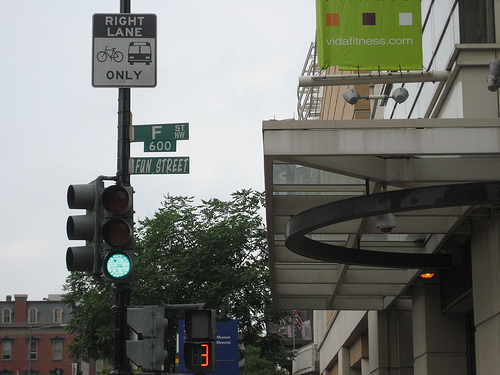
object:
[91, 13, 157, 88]
sign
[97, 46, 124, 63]
bike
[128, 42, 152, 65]
bus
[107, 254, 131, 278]
light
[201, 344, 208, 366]
three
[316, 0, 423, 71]
sign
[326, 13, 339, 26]
square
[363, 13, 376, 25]
square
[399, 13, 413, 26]
square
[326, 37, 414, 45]
writing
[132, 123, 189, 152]
sign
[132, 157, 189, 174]
sign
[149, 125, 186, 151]
writing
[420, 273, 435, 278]
light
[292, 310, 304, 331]
flag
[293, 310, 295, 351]
pole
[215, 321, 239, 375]
sign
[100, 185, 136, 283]
light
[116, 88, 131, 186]
pole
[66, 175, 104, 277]
light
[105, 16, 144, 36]
writing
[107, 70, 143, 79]
writing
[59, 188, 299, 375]
tree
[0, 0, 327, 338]
sky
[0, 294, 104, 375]
building